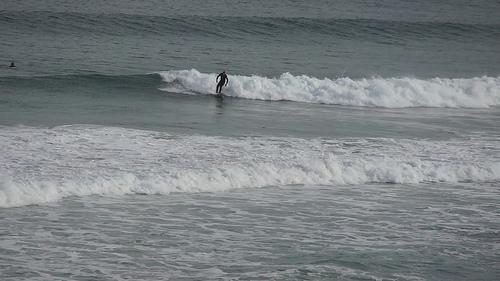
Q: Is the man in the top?
A: Yes, the man is in the top of the image.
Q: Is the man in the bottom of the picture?
A: No, the man is in the top of the image.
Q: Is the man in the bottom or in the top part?
A: The man is in the top of the image.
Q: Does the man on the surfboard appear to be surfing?
A: Yes, the man is surfing.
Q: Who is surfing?
A: The man is surfing.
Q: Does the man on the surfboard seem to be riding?
A: No, the man is surfing.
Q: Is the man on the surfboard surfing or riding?
A: The man is surfing.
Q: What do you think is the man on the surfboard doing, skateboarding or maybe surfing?
A: The man is surfing.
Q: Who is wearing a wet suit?
A: The man is wearing a wet suit.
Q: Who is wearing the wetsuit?
A: The man is wearing a wet suit.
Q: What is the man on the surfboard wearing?
A: The man is wearing a wet suit.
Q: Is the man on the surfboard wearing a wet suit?
A: Yes, the man is wearing a wet suit.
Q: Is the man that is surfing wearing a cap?
A: No, the man is wearing a wet suit.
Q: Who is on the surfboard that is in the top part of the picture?
A: The man is on the surf board.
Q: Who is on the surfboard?
A: The man is on the surf board.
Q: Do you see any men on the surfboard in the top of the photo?
A: Yes, there is a man on the surfboard.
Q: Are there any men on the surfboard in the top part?
A: Yes, there is a man on the surfboard.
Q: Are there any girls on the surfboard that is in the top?
A: No, there is a man on the surfboard.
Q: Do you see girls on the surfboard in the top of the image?
A: No, there is a man on the surfboard.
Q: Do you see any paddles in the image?
A: No, there are no paddles.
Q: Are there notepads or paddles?
A: No, there are no paddles or notepads.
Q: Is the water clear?
A: Yes, the water is clear.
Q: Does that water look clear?
A: Yes, the water is clear.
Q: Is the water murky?
A: No, the water is clear.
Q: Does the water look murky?
A: No, the water is clear.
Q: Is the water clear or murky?
A: The water is clear.